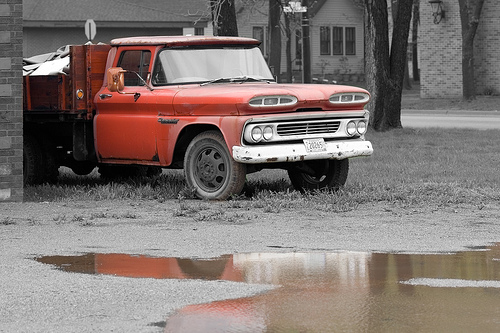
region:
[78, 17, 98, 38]
Back of a stop sign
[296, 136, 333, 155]
Front license plate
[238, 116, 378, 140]
Front grill with headlights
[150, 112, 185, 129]
Manufacturer's logo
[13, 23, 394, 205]
Old pick-up truck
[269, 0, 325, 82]
Street sign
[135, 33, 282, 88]
Windshield made of tinted glass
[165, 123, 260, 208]
An almost flat passenger front tire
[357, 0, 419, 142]
Mature tree with split trunk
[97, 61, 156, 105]
Passenger side view mirror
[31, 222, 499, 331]
pool of water on the ground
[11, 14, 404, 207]
old red pickup truck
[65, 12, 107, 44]
stop sign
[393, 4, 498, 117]
building made of brick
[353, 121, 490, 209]
grass on the ground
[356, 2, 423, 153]
tree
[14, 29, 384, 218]
rusty pickup truck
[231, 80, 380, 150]
two sets of headlights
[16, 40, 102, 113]
the bed of truck is full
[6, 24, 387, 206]
truck parked next to a brick building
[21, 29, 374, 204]
Old red pick up truck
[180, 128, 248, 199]
Dirty black truck tire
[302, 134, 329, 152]
Black and white license plate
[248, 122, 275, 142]
Pair clear round headlights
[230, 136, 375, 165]
Chipped white truck bumper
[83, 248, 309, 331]
Reflection of truck in water puddle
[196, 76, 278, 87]
Windshield wipers on truck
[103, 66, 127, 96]
Orange sideview truck mirror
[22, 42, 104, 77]
Cargo on pickup truck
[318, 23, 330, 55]
Rectangle house window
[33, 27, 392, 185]
Old red truck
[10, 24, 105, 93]
Debris in a truckbed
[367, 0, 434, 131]
Tree in the background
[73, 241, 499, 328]
Puddle on the road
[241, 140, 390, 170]
Rust on a truck's bumper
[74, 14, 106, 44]
The back of a stop sign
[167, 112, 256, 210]
black tire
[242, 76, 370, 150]
a red truck's grill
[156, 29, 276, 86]
light reflected off of a windshield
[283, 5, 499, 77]
houses in a neighborhood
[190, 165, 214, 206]
wheel of a car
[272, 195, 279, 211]
part of the grass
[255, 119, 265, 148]
light of a car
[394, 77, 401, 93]
stem of a tree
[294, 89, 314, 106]
bonnet of a car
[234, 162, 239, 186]
tire of a car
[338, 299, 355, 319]
section of small water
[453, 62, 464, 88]
edge of a building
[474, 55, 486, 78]
part of a building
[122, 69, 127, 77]
part of a side mirror